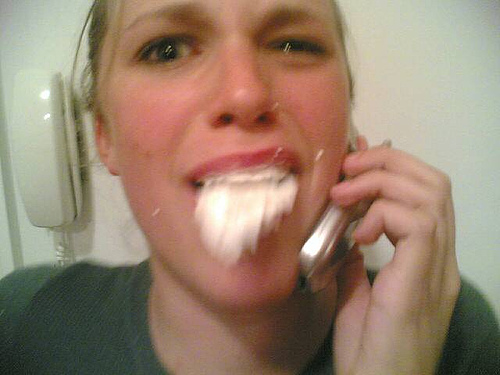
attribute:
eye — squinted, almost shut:
[138, 37, 200, 73]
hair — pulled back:
[71, 1, 356, 111]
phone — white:
[1, 66, 95, 233]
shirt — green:
[4, 263, 494, 373]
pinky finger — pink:
[344, 195, 441, 271]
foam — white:
[192, 175, 299, 262]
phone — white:
[301, 119, 397, 296]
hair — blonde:
[67, 0, 348, 161]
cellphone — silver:
[294, 122, 399, 307]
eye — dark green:
[137, 39, 197, 65]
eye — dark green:
[271, 37, 327, 57]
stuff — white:
[207, 179, 280, 241]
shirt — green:
[50, 260, 476, 371]